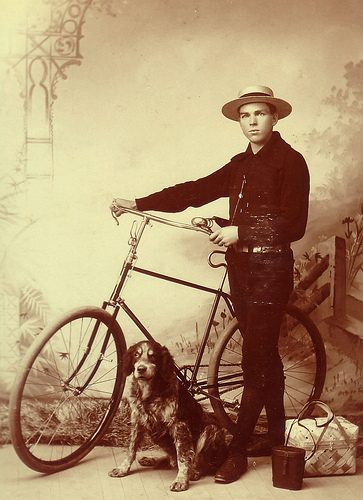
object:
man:
[109, 82, 311, 483]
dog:
[105, 336, 229, 491]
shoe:
[210, 450, 250, 483]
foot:
[212, 448, 250, 484]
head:
[120, 337, 174, 385]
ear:
[158, 343, 175, 384]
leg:
[169, 423, 191, 493]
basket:
[283, 399, 363, 492]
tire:
[206, 296, 332, 457]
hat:
[220, 83, 294, 122]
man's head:
[220, 81, 296, 146]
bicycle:
[7, 195, 329, 476]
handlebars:
[105, 194, 243, 256]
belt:
[227, 242, 292, 254]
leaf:
[107, 428, 113, 436]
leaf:
[91, 409, 95, 415]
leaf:
[120, 411, 125, 418]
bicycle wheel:
[6, 301, 129, 476]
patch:
[269, 441, 306, 492]